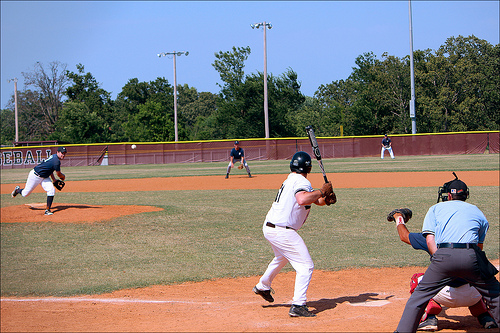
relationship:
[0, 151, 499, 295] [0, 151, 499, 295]
grass in grass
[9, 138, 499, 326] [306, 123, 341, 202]
player has bat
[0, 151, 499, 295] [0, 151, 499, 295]
grass on grass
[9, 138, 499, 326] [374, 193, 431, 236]
player has a mitt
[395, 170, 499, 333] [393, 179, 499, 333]
umpire behind umpire